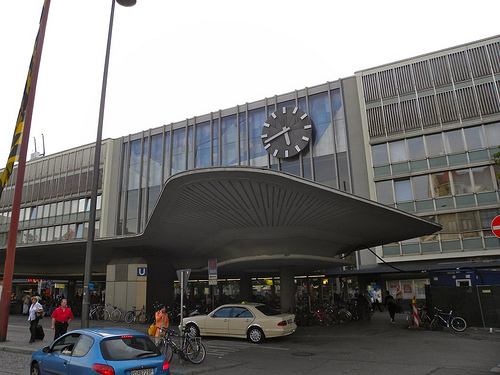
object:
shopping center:
[0, 31, 500, 320]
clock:
[259, 104, 317, 160]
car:
[180, 298, 298, 344]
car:
[30, 325, 176, 375]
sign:
[136, 267, 148, 277]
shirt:
[53, 304, 76, 324]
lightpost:
[80, 0, 139, 328]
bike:
[427, 307, 469, 333]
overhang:
[143, 163, 449, 266]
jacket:
[156, 309, 172, 337]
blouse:
[27, 301, 44, 320]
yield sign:
[175, 268, 192, 288]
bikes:
[155, 324, 208, 366]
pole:
[412, 295, 421, 328]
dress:
[151, 306, 174, 340]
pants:
[54, 321, 70, 345]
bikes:
[407, 307, 431, 325]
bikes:
[123, 305, 154, 326]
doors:
[216, 277, 241, 302]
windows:
[368, 140, 393, 169]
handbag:
[149, 321, 155, 337]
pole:
[3, 0, 54, 341]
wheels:
[246, 324, 266, 343]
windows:
[209, 306, 255, 320]